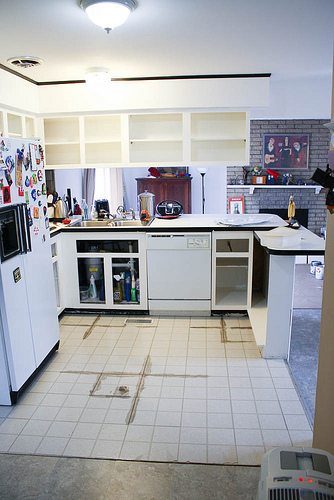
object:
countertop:
[151, 211, 325, 252]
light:
[75, 0, 137, 36]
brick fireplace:
[225, 118, 328, 242]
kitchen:
[0, 0, 334, 499]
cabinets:
[212, 214, 295, 358]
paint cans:
[310, 261, 325, 280]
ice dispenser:
[0, 207, 29, 258]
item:
[241, 166, 250, 185]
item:
[251, 167, 266, 185]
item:
[267, 169, 275, 184]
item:
[281, 173, 293, 185]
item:
[298, 179, 307, 184]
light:
[84, 67, 112, 98]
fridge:
[0, 137, 59, 409]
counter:
[147, 213, 324, 257]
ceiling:
[0, 0, 334, 83]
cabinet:
[75, 240, 139, 254]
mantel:
[227, 185, 322, 195]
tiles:
[170, 368, 187, 378]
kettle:
[53, 196, 69, 223]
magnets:
[0, 137, 48, 241]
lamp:
[195, 167, 210, 214]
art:
[262, 132, 309, 170]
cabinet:
[135, 174, 192, 214]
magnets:
[42, 183, 47, 194]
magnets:
[38, 170, 43, 181]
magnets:
[25, 177, 30, 188]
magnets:
[31, 189, 36, 201]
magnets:
[34, 206, 39, 218]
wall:
[42, 89, 227, 223]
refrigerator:
[0, 136, 59, 404]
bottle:
[89, 274, 98, 298]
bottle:
[131, 275, 137, 301]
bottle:
[126, 273, 131, 301]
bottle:
[120, 274, 126, 300]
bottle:
[112, 275, 123, 302]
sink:
[63, 212, 150, 228]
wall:
[224, 120, 330, 268]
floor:
[0, 313, 260, 500]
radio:
[156, 198, 183, 216]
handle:
[19, 202, 32, 254]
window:
[83, 167, 115, 222]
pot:
[137, 190, 155, 216]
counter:
[146, 213, 211, 317]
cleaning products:
[113, 272, 140, 302]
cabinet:
[77, 257, 139, 303]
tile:
[160, 385, 183, 398]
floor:
[288, 263, 323, 428]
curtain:
[82, 169, 127, 215]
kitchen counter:
[148, 214, 289, 227]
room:
[225, 77, 334, 451]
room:
[0, 115, 227, 500]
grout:
[189, 423, 221, 463]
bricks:
[245, 191, 259, 213]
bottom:
[61, 232, 253, 316]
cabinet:
[0, 108, 249, 172]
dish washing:
[288, 195, 295, 221]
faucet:
[99, 209, 115, 219]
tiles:
[61, 313, 266, 451]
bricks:
[250, 121, 263, 164]